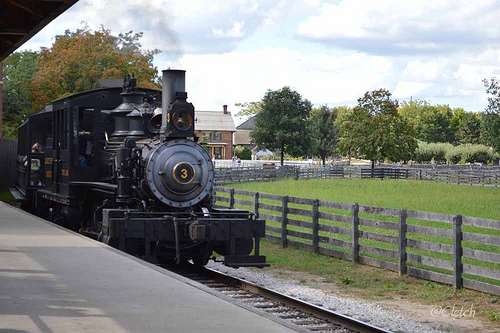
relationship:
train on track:
[0, 70, 267, 273] [197, 266, 384, 332]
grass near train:
[348, 178, 412, 220] [0, 70, 267, 273]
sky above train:
[211, 2, 446, 82] [0, 70, 267, 273]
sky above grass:
[211, 2, 446, 82] [348, 178, 412, 220]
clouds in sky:
[184, 47, 353, 94] [22, 5, 494, 99]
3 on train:
[172, 158, 199, 188] [0, 70, 267, 273]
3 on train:
[181, 169, 188, 179] [0, 70, 267, 273]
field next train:
[219, 178, 495, 227] [4, 56, 273, 279]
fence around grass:
[230, 185, 499, 274] [348, 178, 412, 220]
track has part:
[197, 264, 364, 331] [259, 293, 277, 302]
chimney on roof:
[219, 100, 228, 118] [188, 113, 237, 134]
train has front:
[8, 62, 235, 271] [141, 131, 222, 216]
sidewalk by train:
[4, 211, 273, 329] [4, 56, 273, 279]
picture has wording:
[1, 4, 497, 329] [422, 294, 480, 328]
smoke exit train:
[101, 5, 186, 61] [0, 70, 267, 273]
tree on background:
[182, 98, 496, 150] [153, 91, 489, 136]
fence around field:
[215, 188, 499, 297] [226, 169, 498, 236]